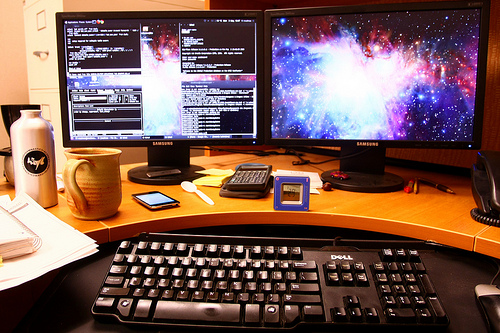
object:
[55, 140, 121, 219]
mug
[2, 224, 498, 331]
shelf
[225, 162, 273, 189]
calculator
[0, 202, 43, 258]
notebook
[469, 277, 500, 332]
mouse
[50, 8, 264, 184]
computer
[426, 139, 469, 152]
ground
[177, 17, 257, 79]
window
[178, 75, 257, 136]
window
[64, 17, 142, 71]
window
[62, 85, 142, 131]
window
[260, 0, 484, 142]
screen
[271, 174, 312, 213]
cellphone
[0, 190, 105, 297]
papers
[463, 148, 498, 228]
phone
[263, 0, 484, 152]
monitors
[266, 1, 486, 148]
black frames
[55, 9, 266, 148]
black frames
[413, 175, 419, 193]
pencil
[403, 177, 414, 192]
pens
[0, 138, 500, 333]
desk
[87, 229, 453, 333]
keyboard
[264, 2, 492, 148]
computer monitor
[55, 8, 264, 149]
computer monitor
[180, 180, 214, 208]
spoon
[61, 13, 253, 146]
monitor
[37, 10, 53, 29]
picture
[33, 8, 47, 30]
frame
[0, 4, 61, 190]
wall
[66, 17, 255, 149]
information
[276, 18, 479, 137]
picture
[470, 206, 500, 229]
cord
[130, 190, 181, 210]
phone